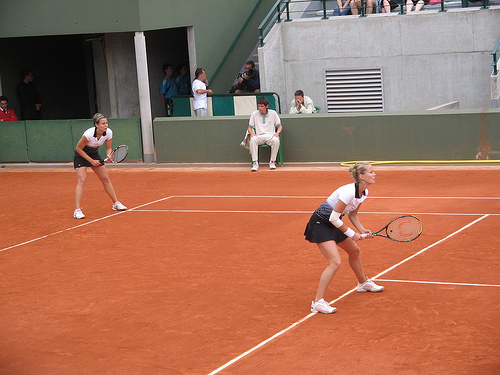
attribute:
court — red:
[0, 170, 497, 372]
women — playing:
[52, 98, 443, 318]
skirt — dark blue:
[71, 144, 106, 168]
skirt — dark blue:
[303, 206, 349, 244]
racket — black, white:
[99, 144, 131, 167]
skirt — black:
[74, 143, 106, 168]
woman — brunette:
[72, 110, 126, 218]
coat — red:
[0, 109, 20, 123]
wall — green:
[2, 114, 145, 164]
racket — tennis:
[365, 213, 430, 257]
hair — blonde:
[343, 152, 369, 176]